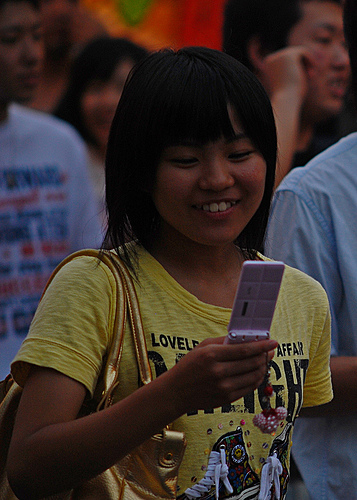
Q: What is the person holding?
A: Cell phone.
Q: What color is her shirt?
A: Yellow.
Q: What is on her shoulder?
A: Purse.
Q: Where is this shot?
A: Crowd.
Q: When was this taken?
A: Daytime.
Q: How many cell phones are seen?
A: 2.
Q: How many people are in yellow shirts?
A: 1.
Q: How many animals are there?
A: 0.